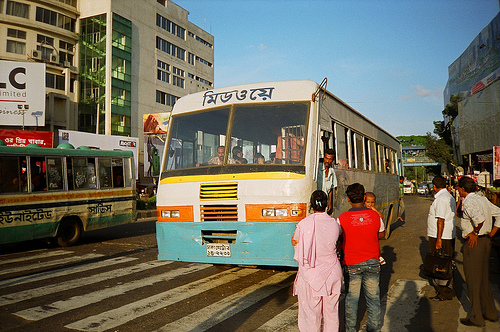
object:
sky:
[352, 0, 443, 110]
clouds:
[396, 79, 437, 101]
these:
[2, 120, 421, 211]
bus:
[156, 81, 401, 267]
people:
[292, 169, 500, 331]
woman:
[297, 190, 342, 330]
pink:
[293, 211, 337, 332]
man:
[339, 183, 381, 332]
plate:
[206, 244, 230, 257]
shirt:
[428, 189, 455, 239]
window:
[232, 102, 305, 165]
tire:
[56, 216, 80, 247]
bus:
[0, 144, 135, 246]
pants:
[464, 236, 489, 331]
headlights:
[170, 210, 180, 218]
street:
[0, 186, 500, 328]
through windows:
[169, 101, 308, 165]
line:
[0, 255, 145, 287]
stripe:
[0, 249, 417, 331]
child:
[365, 192, 376, 208]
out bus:
[300, 149, 319, 187]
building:
[75, 0, 214, 111]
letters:
[203, 91, 217, 106]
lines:
[129, 263, 261, 319]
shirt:
[339, 209, 385, 263]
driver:
[318, 150, 336, 195]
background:
[0, 0, 499, 153]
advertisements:
[0, 62, 46, 126]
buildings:
[2, 0, 80, 153]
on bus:
[289, 142, 336, 210]